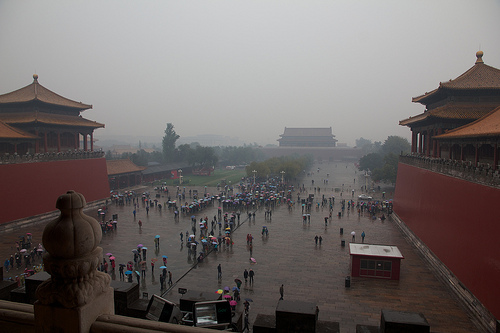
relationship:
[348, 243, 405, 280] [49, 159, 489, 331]
building in road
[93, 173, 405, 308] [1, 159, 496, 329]
people gathered in square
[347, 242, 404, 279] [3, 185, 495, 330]
building in square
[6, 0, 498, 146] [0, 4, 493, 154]
clouds in sky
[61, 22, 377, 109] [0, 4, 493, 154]
clouds in sky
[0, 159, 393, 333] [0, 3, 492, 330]
people walking outside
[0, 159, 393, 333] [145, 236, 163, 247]
people holding umbrella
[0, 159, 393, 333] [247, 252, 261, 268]
people holding umbrellas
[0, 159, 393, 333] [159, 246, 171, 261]
people holding umbrellas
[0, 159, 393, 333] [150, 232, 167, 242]
people holding umbrellas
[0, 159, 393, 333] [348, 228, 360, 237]
people holding umbrellas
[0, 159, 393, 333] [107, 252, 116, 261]
people holding umbrellas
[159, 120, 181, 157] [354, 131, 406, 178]
tree with leaves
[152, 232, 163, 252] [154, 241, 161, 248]
boy in a blue shirt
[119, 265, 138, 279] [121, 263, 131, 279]
boy in a shirt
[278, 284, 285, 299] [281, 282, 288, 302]
boy in a shirt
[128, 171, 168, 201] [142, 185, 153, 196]
boy in a shirt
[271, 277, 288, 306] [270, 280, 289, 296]
boy riding around in shirt